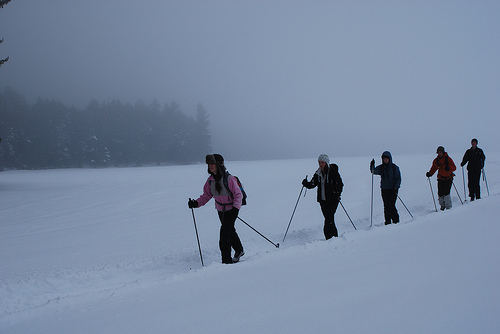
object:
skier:
[188, 153, 248, 265]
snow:
[0, 152, 499, 334]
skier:
[299, 153, 343, 240]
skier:
[366, 151, 402, 226]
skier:
[423, 146, 457, 211]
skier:
[458, 137, 486, 202]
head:
[317, 153, 330, 171]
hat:
[317, 154, 330, 167]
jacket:
[195, 174, 244, 212]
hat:
[205, 153, 224, 165]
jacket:
[428, 153, 457, 178]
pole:
[188, 198, 206, 266]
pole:
[237, 215, 281, 247]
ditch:
[4, 184, 497, 324]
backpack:
[232, 174, 247, 205]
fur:
[205, 154, 217, 164]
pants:
[216, 209, 244, 263]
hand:
[187, 199, 197, 209]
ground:
[0, 153, 499, 333]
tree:
[82, 98, 112, 167]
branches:
[105, 145, 110, 162]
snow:
[103, 148, 111, 164]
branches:
[92, 145, 103, 166]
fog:
[0, 0, 499, 170]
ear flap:
[217, 165, 225, 175]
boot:
[233, 249, 246, 262]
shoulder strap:
[222, 173, 234, 198]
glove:
[188, 199, 199, 209]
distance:
[1, 1, 500, 170]